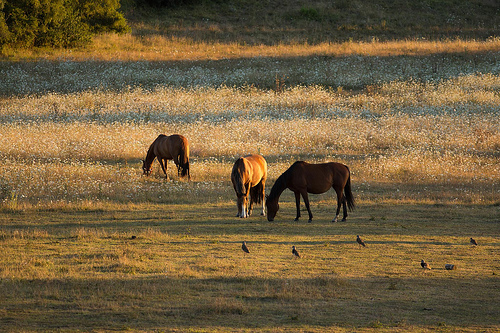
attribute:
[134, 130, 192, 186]
horse — grazing, eating grass, lonely, eating, brown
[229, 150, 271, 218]
horse — grazing, brown, light brown, eating grass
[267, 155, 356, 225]
horse — grazing, brown, eating, dark brown, eating grass, big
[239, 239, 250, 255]
bird — little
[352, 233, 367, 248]
bird — little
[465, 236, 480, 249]
bird — little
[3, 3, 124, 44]
bushes — green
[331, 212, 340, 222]
hoof — white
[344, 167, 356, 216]
tail — black, long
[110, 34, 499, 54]
area — sunny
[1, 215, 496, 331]
grass — low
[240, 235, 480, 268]
birds — standing, watching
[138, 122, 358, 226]
horses — facing, looking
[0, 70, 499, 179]
flowers — white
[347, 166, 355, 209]
tail — black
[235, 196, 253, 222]
horse's head — low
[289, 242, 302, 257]
bird — little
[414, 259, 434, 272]
bird — little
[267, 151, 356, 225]
horses' color — brown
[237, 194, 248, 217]
face — white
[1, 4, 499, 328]
scene — outdoors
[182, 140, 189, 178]
tail — black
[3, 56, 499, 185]
grass — tall, brown, green